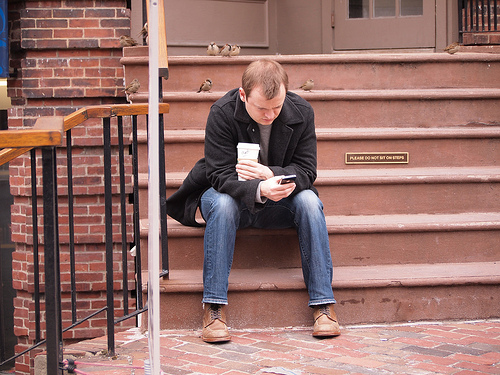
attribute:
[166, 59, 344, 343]
man — sitting, sitting down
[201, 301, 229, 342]
shoe — brown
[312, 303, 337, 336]
shoe — brown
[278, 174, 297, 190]
cell phone — hand held, black, apple brand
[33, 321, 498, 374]
ground — made of bricks, red brick, diagonal laid brick, red, brick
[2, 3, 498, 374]
building — red bricked, red brick, brick stained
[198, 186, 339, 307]
jeans — blue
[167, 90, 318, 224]
jacket — black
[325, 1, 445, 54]
door — wood, glass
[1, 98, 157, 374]
railing — wood, metal, black iron